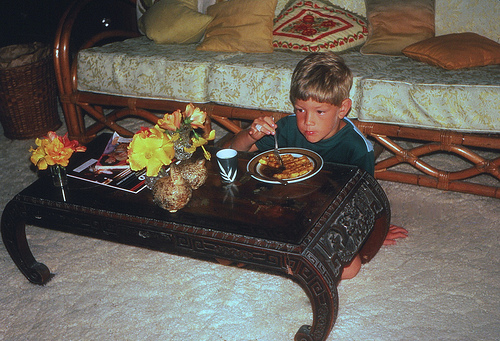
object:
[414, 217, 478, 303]
carpet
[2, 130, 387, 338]
coffee table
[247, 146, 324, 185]
dinner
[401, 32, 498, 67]
pillows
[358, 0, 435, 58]
pillows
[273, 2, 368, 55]
pillows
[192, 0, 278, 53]
pillows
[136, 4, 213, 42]
pillows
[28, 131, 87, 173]
arrangement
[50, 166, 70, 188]
container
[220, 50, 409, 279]
boy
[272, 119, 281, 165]
fork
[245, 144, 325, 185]
blue/brown plate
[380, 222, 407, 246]
hand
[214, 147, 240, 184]
cup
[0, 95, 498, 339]
ground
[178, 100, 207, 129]
flower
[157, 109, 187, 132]
flower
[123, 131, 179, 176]
flower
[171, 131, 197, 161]
vase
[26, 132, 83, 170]
flower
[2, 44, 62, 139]
basket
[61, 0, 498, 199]
couch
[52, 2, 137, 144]
arm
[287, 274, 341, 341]
table legs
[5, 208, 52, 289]
table legs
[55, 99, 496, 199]
wooden base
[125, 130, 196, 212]
flower arrangement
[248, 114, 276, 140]
hand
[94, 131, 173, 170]
magazine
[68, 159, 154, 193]
magazine